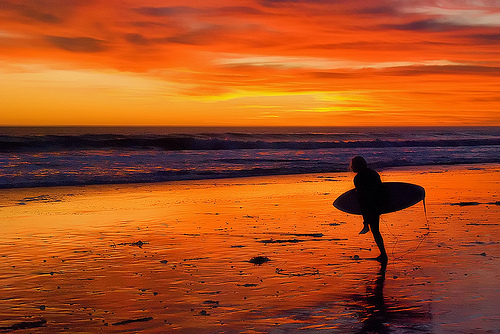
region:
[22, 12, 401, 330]
The sky is orange, yellow and red in color.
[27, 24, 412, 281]
Picture is taken outside.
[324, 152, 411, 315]
The person appears as a shadow.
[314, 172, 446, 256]
The person is holding a surf board.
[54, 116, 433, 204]
The person is walking towards the ocean.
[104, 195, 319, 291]
The sand is reflecting the colors of the sky.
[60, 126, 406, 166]
The water appears purple and red.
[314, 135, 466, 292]
The person appears black.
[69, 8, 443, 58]
The clouds are whispy.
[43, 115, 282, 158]
A wave is breaking in the ocean.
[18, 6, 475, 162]
beautiful sunset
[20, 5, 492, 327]
a very tall tree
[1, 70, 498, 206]
a very tall tree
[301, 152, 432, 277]
a woman on the beach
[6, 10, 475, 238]
beautiful sunny day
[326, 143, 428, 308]
sarfing at at the beach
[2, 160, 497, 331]
a very beautiful beach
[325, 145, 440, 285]
a very pretty woman sarfing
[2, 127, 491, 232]
a very beautiful coastline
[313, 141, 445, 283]
person is holding a surfboard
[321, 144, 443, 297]
person is standing on the beach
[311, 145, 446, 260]
person is standing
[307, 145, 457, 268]
person is looking in the distance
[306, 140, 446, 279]
person is looking at the sunset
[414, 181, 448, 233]
water dripping off the surfboard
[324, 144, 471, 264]
person is slightly tilted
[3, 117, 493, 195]
body of water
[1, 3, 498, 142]
orange sky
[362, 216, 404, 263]
leg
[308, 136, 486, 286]
Surfer on the beach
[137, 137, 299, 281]
sand and water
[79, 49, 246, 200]
sunset on the beach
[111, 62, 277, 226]
evening on the beach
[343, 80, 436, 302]
surfer with his board.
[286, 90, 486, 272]
surfing in the evening.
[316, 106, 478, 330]
walking on the beach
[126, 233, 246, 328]
footprints in the sand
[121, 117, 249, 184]
ocean water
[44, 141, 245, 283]
waves on the beach in the evening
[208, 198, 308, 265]
part of a shore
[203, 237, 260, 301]
part of a reflection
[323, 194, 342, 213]
edge of a swimming board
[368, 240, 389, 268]
part f a leg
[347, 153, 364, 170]
part of some hair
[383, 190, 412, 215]
edge of the board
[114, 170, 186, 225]
edge of a shore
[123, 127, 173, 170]
part of some waves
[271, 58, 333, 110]
part some clouds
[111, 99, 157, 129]
part of the sky